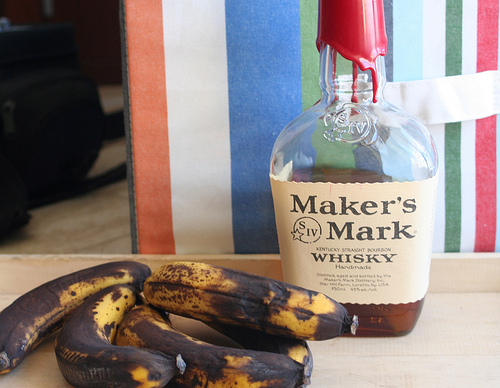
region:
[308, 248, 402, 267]
word "whisky" on bottle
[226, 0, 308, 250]
blue stripe on wall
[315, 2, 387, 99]
red wax on bottle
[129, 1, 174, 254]
orange stripe on wall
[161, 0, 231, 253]
thickest white stripe on wall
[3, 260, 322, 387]
four rotten bananas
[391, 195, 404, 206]
apostrophe on bottle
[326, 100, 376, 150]
embossed circle in glass on bottle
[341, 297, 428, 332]
liquid visible at bottom of glass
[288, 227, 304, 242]
star on bottle label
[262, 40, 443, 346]
A bottle of Maker's Mark whisky.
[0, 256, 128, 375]
An over ripe banana.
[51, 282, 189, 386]
An over ripe banana.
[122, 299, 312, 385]
An over ripe banana.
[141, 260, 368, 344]
An over ripe banana.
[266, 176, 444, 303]
The lable on the bottle of whisky.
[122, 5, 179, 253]
An orange stripe behind the bananas.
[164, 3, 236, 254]
A white stripe behind the bananas.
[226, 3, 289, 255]
A blue stripe behind the bananas and whisky.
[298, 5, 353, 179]
A green striple behind the whisky.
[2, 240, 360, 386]
Four over ripe bananas.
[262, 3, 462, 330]
A glass whisky bottle.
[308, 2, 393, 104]
Dark pink top on glass bottle.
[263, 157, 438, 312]
Label on whisky bottle.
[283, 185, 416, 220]
The word Maker's on bottle.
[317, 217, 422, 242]
The word Mark on bottle.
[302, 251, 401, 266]
The word WHISKY on bottle.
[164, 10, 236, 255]
A wide white vertical stripe.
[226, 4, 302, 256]
A wide blue vertical stripe.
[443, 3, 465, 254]
A narrow green vertical stripe.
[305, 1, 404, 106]
The wax is red.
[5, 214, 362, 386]
The banana is bruised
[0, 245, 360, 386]
The banana is yellow and brown.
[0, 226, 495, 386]
Bananas on a table.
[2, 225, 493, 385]
The table is brown.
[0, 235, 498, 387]
The table is wooden.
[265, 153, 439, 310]
The label is tan.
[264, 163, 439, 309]
the text is black.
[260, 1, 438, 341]
The bottle is clear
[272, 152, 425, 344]
The whiskey is brown.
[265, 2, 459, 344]
bottle of liquor on wooden counter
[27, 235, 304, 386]
over ripened bananas on wooden shelf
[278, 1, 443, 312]
red top on bottle of liquor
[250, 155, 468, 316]
label on liquor bottle says Maker's Mark Whisky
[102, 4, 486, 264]
multi-colored striped wall behind liquor bottle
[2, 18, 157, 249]
black bag in photograph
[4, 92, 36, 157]
zipper on black bag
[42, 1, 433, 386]
bunch of bananas next to liquor bottle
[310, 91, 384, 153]
emblem stamped on liquor bottle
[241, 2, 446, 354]
golden liquor in clear bottle